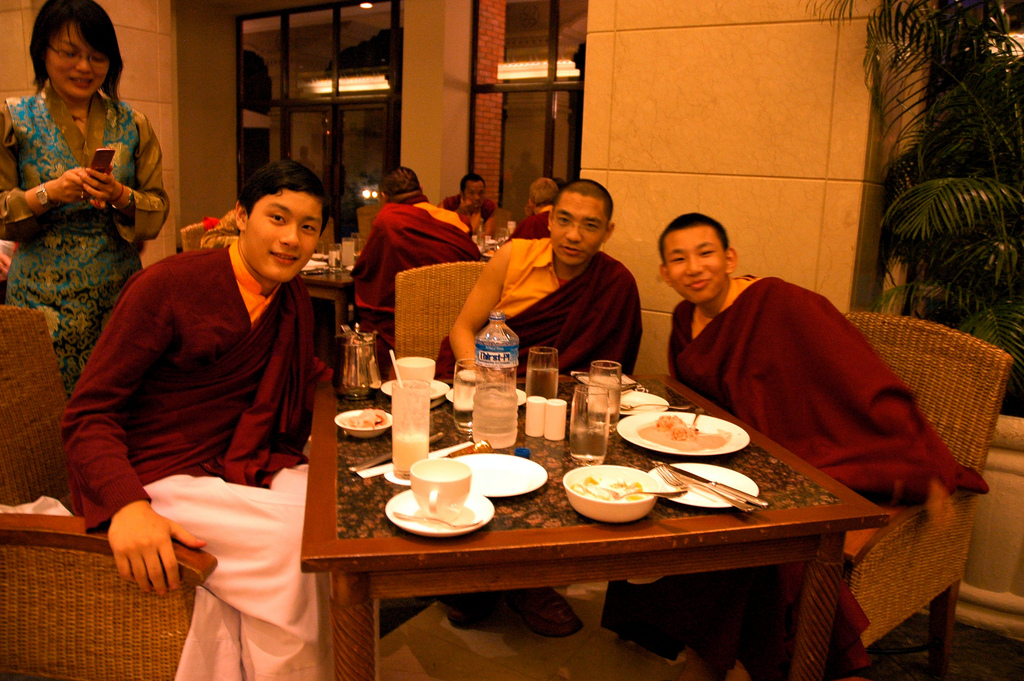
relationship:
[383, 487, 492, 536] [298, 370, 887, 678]
dish on table